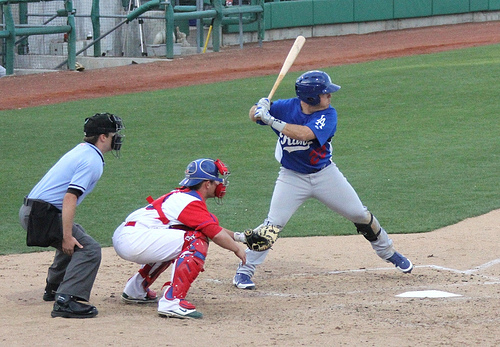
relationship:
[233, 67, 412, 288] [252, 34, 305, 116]
batter has a bat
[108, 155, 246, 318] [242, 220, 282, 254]
catcher has glove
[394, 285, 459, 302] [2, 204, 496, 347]
home plate in dirt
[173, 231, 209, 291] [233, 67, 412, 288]
kneepad on batter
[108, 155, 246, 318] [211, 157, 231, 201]
catcher has a red mask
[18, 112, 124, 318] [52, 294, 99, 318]
empire has a black shoe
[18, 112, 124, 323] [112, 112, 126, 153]
umpire has a mask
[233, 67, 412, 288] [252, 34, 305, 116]
batter has bat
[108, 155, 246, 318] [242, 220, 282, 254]
catcher has a glove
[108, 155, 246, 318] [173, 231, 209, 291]
catcher has red kneepad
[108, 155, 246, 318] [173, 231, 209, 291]
catcher has kneepad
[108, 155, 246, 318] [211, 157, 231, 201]
catcher wearing a mask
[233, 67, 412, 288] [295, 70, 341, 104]
batter has helmet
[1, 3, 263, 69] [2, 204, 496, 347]
fence by dirt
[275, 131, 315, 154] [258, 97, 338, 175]
team name on jersey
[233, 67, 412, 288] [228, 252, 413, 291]
batter has shoes